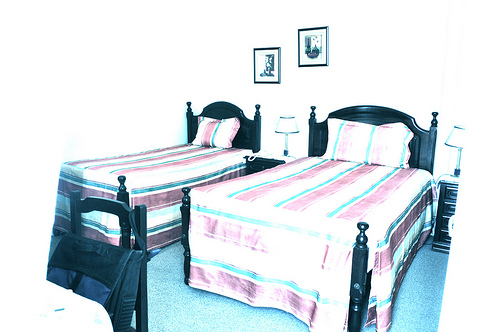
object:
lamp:
[272, 116, 300, 158]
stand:
[241, 148, 299, 175]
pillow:
[192, 115, 239, 147]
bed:
[54, 100, 262, 255]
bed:
[178, 104, 440, 332]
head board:
[305, 104, 440, 174]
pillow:
[318, 116, 416, 170]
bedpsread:
[187, 156, 438, 332]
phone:
[255, 147, 275, 158]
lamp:
[439, 124, 469, 178]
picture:
[296, 26, 329, 67]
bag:
[42, 230, 145, 331]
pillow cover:
[320, 117, 413, 170]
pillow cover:
[191, 116, 241, 149]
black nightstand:
[430, 180, 461, 254]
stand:
[430, 172, 460, 255]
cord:
[248, 153, 260, 162]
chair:
[45, 176, 148, 332]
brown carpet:
[143, 233, 448, 332]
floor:
[146, 237, 448, 332]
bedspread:
[53, 143, 248, 251]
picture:
[253, 47, 279, 85]